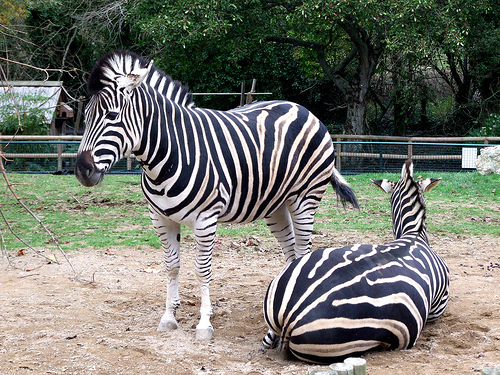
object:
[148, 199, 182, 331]
legs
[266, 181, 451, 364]
black stripe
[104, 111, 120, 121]
eye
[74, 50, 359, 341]
zebra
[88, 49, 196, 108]
mane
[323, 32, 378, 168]
tree trunk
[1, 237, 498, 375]
dirt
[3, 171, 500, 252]
grass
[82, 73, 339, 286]
black stripe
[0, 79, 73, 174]
building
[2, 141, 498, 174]
fence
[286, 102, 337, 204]
back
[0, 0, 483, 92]
leaves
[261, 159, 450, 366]
zebra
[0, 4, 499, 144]
tree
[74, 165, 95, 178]
nose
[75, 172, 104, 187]
mouth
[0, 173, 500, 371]
ground